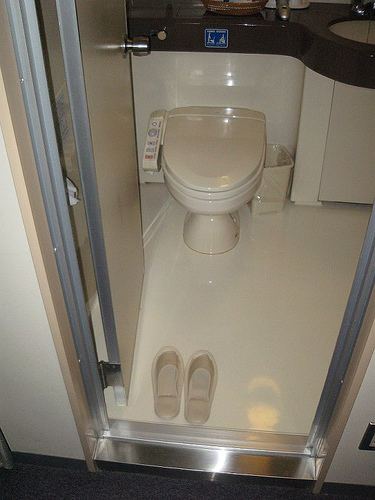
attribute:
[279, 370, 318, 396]
flooring — section, small, white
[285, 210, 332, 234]
flooring — section, small, white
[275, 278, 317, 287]
flooring — section, small, white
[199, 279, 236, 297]
flooring — section, small, white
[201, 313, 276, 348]
flooring — section, small, white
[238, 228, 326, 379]
flooring — white, small, section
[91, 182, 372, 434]
floor — section, small, white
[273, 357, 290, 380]
floor — small, section, white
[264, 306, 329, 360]
section — small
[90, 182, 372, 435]
flooring — small, white, section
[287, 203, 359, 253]
flooring — white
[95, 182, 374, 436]
white flooring — small, section